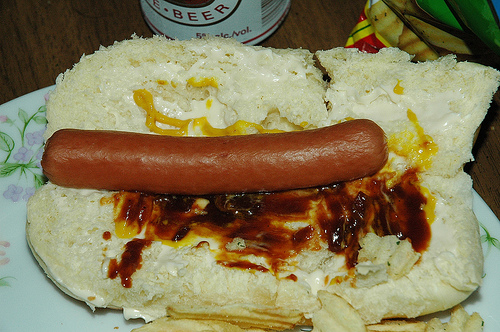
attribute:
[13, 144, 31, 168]
flower — pink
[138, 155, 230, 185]
smokie — long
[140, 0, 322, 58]
can — beer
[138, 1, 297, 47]
can — round, white, black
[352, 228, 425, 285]
chip — potato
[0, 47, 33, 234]
plate — WHITE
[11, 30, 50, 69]
table — wood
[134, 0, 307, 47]
beer — white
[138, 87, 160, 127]
mustard — Yellow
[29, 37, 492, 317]
bun — high-carb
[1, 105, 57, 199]
flowers — purple and green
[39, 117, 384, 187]
sausage — LONG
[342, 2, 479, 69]
bag — plastic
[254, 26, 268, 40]
part — bottom